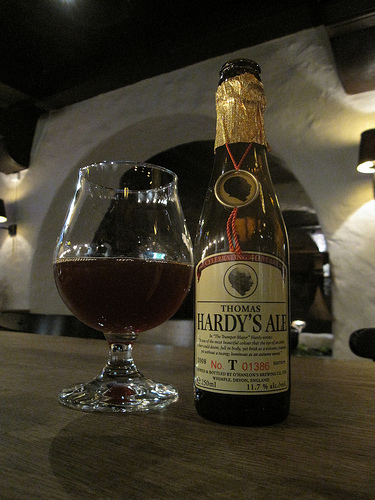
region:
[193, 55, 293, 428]
brown bottle of ale with a tan label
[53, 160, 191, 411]
clear glass with brown ale in it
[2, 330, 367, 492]
wood grain dark brown table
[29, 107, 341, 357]
white cement archway made of a very thick wall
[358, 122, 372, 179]
black lamp with a bright lightbulb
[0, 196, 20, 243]
black lamp with a bright white light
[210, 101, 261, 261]
red string holding a gold round medallion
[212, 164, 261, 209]
round gold medallion with a black silhouette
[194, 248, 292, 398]
black and red text on a tan label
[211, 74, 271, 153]
gold foil around the neck of a brown bottles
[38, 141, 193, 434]
a wine in the glass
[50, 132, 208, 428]
a glass on the table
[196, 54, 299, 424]
bottle of ale on table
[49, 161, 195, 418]
wine glass filled with ale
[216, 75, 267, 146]
gold foil on bottle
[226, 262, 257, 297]
picture of old man on bottle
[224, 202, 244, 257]
red ribbon on bottle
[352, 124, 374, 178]
light fixture on the wall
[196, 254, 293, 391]
label on the bottle of ale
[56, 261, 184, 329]
liquid inside of the glass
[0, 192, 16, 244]
black light fixture on the wall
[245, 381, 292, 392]
alcohol content printed on label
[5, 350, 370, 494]
wooden table with dark grain markings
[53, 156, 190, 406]
curved and stemmed glass half full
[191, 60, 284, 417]
brown bottle with label, red string, silhouette and metal covering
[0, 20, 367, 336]
thick archway on textured white wall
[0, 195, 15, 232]
lighting fixture on wall with edge of black shade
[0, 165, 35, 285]
ovals of light on wall from fixture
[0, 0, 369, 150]
black ceiling over archway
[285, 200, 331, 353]
white surface by round object by window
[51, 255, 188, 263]
broken line of bubbles on edge of brown liquid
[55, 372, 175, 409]
bumpy glass surface on base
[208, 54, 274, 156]
the neck of a liquor bottle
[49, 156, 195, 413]
a half full glass of liquor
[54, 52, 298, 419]
a bottle of liquor next to a glass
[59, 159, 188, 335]
a glass of brown liquor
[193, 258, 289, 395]
a descriptive logo on a liquor bottle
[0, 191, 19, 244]
a bright black lamp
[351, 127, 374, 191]
a bright brown lamp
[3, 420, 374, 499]
a wooden table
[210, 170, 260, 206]
a bottlecap with a logo on it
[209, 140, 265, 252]
a red string with a circular logo